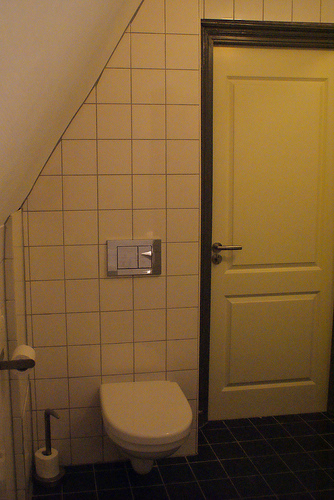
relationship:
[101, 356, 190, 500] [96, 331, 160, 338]
porcelain toilet toilet that attached to wall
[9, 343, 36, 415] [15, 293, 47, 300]
toilet paper holder on side of wall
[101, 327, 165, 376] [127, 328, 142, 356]
four square white tiles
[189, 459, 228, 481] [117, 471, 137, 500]
tile on floor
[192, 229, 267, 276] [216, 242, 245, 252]
long silver door door handle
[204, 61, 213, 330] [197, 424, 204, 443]
dark wooden door frame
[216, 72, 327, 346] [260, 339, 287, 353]
door with a yellowish tint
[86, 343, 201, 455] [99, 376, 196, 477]
modern white porcelain toilet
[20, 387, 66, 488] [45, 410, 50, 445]
toilet paper roll holder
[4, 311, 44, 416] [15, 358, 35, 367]
toilet paper roll holder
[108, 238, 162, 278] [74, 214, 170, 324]
silver rectangle on wall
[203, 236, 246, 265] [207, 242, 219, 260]
door handle and lock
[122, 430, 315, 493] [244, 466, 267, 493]
tile on bathroom floor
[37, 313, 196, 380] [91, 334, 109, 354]
cream colored tile on bathroom wall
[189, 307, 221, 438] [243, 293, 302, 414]
trim around bathroom door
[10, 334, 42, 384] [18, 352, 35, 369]
roll of white toilet paper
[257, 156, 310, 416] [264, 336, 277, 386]
yellowish two panel door